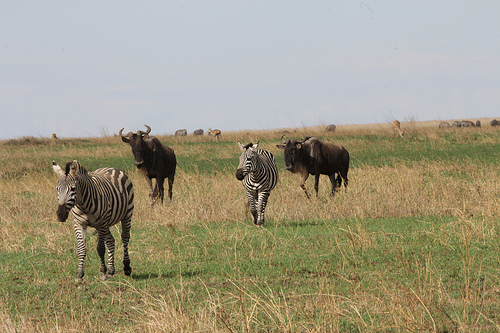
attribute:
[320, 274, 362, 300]
grass — green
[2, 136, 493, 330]
field — grassy 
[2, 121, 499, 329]
area — grass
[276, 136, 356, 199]
buffalo — brown